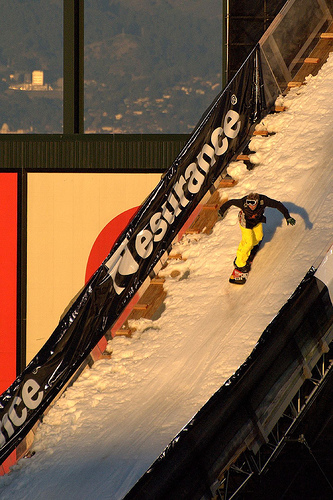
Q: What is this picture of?
A: A skier going down a slope.